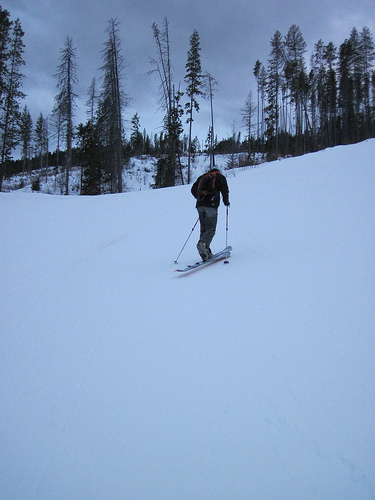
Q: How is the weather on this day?
A: It is cloudy.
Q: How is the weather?
A: It is cloudy.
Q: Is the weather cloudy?
A: Yes, it is cloudy.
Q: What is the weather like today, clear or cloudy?
A: It is cloudy.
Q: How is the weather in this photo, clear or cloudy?
A: It is cloudy.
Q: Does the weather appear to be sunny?
A: No, it is cloudy.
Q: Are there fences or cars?
A: No, there are no fences or cars.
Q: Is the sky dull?
A: Yes, the sky is dull.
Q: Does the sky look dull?
A: Yes, the sky is dull.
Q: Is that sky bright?
A: No, the sky is dull.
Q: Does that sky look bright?
A: No, the sky is dull.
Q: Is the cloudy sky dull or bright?
A: The sky is dull.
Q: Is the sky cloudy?
A: Yes, the sky is cloudy.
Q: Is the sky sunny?
A: No, the sky is cloudy.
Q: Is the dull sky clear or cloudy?
A: The sky is cloudy.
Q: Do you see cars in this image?
A: No, there are no cars.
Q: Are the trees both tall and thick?
A: No, the trees are tall but thin.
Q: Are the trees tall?
A: Yes, the trees are tall.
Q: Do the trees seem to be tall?
A: Yes, the trees are tall.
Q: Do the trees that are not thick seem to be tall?
A: Yes, the trees are tall.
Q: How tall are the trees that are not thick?
A: The trees are tall.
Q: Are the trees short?
A: No, the trees are tall.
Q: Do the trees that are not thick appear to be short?
A: No, the trees are tall.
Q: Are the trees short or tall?
A: The trees are tall.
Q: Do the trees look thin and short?
A: No, the trees are thin but tall.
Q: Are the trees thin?
A: Yes, the trees are thin.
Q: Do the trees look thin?
A: Yes, the trees are thin.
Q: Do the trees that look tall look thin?
A: Yes, the trees are thin.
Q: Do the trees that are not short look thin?
A: Yes, the trees are thin.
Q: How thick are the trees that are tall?
A: The trees are thin.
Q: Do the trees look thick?
A: No, the trees are thin.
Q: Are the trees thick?
A: No, the trees are thin.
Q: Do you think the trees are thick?
A: No, the trees are thin.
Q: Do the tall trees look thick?
A: No, the trees are thin.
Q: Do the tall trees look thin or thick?
A: The trees are thin.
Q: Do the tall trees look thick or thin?
A: The trees are thin.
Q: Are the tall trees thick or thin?
A: The trees are thin.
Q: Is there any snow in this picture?
A: Yes, there is snow.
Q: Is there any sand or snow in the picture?
A: Yes, there is snow.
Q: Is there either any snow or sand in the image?
A: Yes, there is snow.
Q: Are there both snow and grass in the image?
A: No, there is snow but no grass.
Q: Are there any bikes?
A: No, there are no bikes.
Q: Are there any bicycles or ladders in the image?
A: No, there are no bicycles or ladders.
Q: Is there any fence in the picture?
A: No, there are no fences.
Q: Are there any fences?
A: No, there are no fences.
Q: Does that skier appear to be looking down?
A: Yes, the skier is looking down.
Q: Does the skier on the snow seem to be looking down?
A: Yes, the skier is looking down.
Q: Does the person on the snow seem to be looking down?
A: Yes, the skier is looking down.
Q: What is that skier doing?
A: The skier is looking down.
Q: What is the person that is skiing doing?
A: The skier is looking down.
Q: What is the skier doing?
A: The skier is looking down.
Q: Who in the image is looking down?
A: The skier is looking down.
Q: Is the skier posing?
A: No, the skier is looking down.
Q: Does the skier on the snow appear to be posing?
A: No, the skier is looking down.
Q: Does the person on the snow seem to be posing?
A: No, the skier is looking down.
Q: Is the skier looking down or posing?
A: The skier is looking down.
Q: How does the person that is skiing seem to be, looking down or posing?
A: The skier is looking down.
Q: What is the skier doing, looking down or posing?
A: The skier is looking down.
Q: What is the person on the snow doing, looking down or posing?
A: The skier is looking down.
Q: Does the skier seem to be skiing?
A: Yes, the skier is skiing.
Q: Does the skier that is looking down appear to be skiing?
A: Yes, the skier is skiing.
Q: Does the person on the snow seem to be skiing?
A: Yes, the skier is skiing.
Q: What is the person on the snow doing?
A: The skier is skiing.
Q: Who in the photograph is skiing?
A: The skier is skiing.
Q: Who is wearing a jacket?
A: The skier is wearing a jacket.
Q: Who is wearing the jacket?
A: The skier is wearing a jacket.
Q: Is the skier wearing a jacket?
A: Yes, the skier is wearing a jacket.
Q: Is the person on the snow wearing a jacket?
A: Yes, the skier is wearing a jacket.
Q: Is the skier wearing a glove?
A: No, the skier is wearing a jacket.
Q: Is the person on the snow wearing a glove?
A: No, the skier is wearing a jacket.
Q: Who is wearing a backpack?
A: The skier is wearing a backpack.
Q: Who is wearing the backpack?
A: The skier is wearing a backpack.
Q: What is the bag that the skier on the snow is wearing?
A: The bag is a backpack.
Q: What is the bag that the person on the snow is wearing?
A: The bag is a backpack.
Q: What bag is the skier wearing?
A: The skier is wearing a backpack.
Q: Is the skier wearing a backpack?
A: Yes, the skier is wearing a backpack.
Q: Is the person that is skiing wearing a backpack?
A: Yes, the skier is wearing a backpack.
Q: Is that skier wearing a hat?
A: No, the skier is wearing a backpack.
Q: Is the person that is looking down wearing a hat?
A: No, the skier is wearing a backpack.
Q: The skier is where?
A: The skier is on the snow.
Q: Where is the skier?
A: The skier is on the snow.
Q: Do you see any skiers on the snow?
A: Yes, there is a skier on the snow.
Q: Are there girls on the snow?
A: No, there is a skier on the snow.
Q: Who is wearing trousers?
A: The skier is wearing trousers.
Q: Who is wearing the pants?
A: The skier is wearing trousers.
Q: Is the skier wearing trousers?
A: Yes, the skier is wearing trousers.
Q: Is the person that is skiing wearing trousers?
A: Yes, the skier is wearing trousers.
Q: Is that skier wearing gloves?
A: No, the skier is wearing trousers.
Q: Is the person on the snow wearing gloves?
A: No, the skier is wearing trousers.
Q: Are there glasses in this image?
A: No, there are no glasses.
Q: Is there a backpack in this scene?
A: Yes, there is a backpack.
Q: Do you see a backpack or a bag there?
A: Yes, there is a backpack.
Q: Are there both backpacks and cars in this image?
A: No, there is a backpack but no cars.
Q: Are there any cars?
A: No, there are no cars.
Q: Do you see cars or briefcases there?
A: No, there are no cars or briefcases.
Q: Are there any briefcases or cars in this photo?
A: No, there are no cars or briefcases.